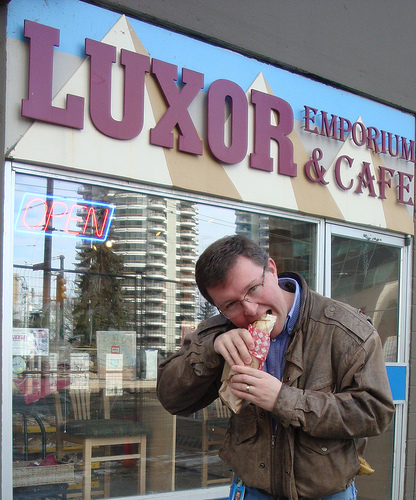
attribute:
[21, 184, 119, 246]
sign — lit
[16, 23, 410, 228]
letters — maroon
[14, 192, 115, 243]
open sign — neon, red, blue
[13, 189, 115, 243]
sign — open, neon, blue, red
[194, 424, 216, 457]
chair — wooden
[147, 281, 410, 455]
shirt — blue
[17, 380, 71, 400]
tablecloth — red, cloth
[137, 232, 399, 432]
he — eating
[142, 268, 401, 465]
jacket — leather, brown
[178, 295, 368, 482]
jacket — leather, brown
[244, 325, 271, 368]
wrapping — checkered, brown